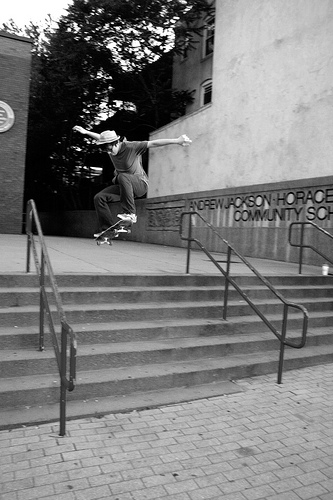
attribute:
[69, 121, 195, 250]
person — skateboarding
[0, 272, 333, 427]
steps — leading down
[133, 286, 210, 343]
stairs — stone 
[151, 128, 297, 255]
wall — concrete 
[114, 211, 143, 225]
sneakers — white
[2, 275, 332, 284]
steps — leading up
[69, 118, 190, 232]
skateboarder — mid air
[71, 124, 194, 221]
person — skateboarding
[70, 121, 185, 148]
arms — out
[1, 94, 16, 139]
sign — round , half 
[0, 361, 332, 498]
sidewalk — bricks